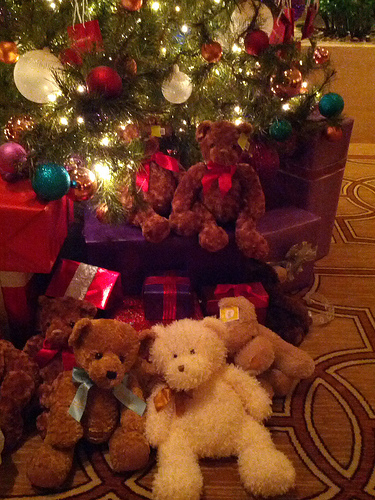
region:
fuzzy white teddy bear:
[147, 314, 297, 493]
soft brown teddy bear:
[30, 317, 148, 475]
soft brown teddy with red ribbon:
[21, 289, 70, 424]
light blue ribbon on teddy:
[65, 363, 143, 423]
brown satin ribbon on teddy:
[154, 379, 200, 415]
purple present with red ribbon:
[133, 264, 204, 321]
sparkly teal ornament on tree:
[30, 156, 71, 201]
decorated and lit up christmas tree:
[10, 5, 250, 103]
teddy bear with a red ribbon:
[178, 114, 286, 257]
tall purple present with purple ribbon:
[284, 112, 357, 264]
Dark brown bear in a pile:
[33, 311, 163, 477]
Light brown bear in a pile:
[137, 326, 313, 497]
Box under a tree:
[39, 251, 141, 320]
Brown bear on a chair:
[171, 101, 299, 261]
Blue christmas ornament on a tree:
[24, 156, 81, 210]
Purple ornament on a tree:
[0, 142, 37, 187]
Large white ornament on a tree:
[8, 47, 60, 108]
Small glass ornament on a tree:
[159, 54, 198, 107]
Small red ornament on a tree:
[191, 34, 229, 60]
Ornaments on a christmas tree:
[223, 23, 357, 145]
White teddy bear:
[159, 326, 295, 495]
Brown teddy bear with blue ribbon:
[67, 324, 147, 419]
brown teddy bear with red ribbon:
[193, 139, 253, 211]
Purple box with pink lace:
[138, 271, 204, 317]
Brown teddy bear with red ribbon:
[38, 301, 80, 372]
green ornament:
[36, 165, 67, 201]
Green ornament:
[315, 94, 347, 118]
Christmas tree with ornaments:
[33, 3, 294, 194]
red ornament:
[83, 63, 134, 102]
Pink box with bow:
[201, 278, 272, 309]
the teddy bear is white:
[143, 303, 296, 495]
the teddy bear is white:
[156, 358, 227, 448]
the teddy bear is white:
[88, 226, 271, 479]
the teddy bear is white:
[139, 280, 232, 483]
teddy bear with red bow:
[166, 126, 300, 263]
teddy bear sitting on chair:
[169, 109, 369, 271]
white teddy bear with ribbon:
[146, 327, 296, 495]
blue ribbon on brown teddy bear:
[69, 318, 156, 481]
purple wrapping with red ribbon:
[138, 269, 213, 331]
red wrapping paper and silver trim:
[50, 248, 135, 316]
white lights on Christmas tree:
[87, 51, 151, 204]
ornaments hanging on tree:
[133, 33, 247, 106]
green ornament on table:
[7, 166, 90, 219]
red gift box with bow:
[205, 277, 297, 332]